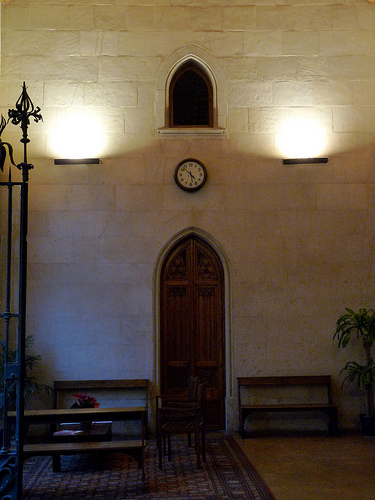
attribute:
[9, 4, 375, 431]
walls — white, tile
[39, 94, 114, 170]
light — white, bright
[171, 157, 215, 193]
clock — brown, black, white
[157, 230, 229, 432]
door — wooden, large, brown, closed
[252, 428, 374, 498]
floor — light brown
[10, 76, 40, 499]
stick — pointy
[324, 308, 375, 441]
potted plant — green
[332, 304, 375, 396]
leaves — green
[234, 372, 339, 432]
bench — brown, wooden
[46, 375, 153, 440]
bench — brown, wooden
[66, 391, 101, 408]
flowers — red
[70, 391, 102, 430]
plant — orange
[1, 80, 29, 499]
fencing — metal, black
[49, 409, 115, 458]
table — brown